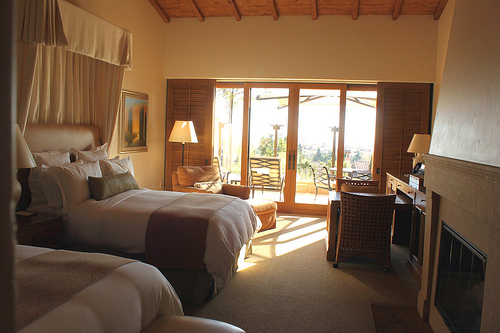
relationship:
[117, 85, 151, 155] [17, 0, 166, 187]
picture on wall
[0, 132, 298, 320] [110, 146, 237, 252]
beds with cover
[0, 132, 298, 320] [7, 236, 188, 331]
beds with cover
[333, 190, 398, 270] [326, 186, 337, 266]
chair with table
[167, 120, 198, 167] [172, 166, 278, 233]
lamp by chair